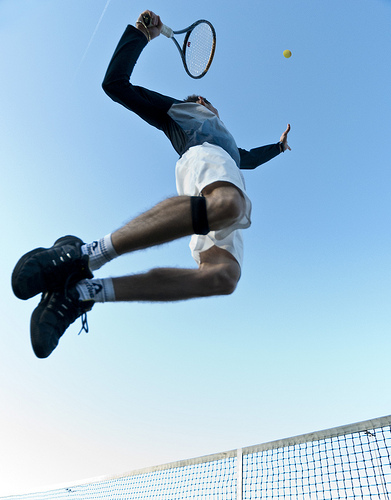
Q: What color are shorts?
A: White.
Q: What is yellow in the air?
A: Tennis ball.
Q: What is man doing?
A: Jumping to hit ball.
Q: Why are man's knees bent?
A: Jumping to hit ball.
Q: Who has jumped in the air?
A: Tennis player.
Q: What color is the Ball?
A: Yellow.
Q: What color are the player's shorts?
A: White.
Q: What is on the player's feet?
A: Sneakers.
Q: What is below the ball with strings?
A: Net.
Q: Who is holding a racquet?
A: Tennis player.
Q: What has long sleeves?
A: Players shirt.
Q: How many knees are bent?
A: 2.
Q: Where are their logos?
A: Socks.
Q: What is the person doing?
A: Hitting a tennis ball.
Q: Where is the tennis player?
A: In the air.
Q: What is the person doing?
A: Playing tennis.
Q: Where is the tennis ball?
A: In the air.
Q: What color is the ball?
A: Yellow.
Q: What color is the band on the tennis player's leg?
A: Black.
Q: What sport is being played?
A: Tennis.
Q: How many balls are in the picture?
A: 1.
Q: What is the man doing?
A: Jumping.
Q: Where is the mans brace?
A: Knee.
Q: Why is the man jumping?
A: Hitting the ball.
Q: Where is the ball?
A: Above the man.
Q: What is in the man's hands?
A: A racquet.